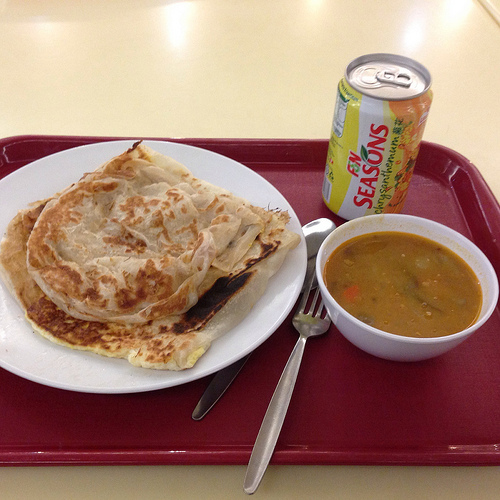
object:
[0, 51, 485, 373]
food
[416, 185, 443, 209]
ground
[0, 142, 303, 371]
bread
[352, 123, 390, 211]
leter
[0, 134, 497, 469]
tray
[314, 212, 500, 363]
bowl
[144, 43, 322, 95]
sheep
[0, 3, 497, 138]
wall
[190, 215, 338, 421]
fork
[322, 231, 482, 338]
soup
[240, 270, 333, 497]
fork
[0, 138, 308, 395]
plate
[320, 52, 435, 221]
can